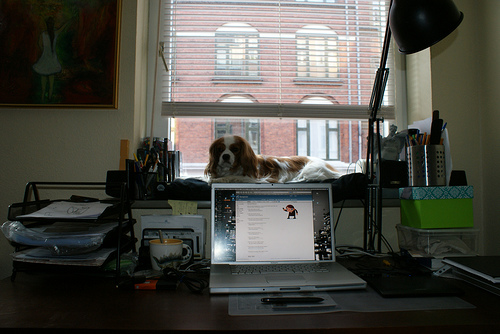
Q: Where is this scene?
A: Room.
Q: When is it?
A: Afternoon.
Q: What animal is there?
A: Dog.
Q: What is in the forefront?
A: Laptop.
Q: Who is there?
A: No one.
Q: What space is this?
A: Office.